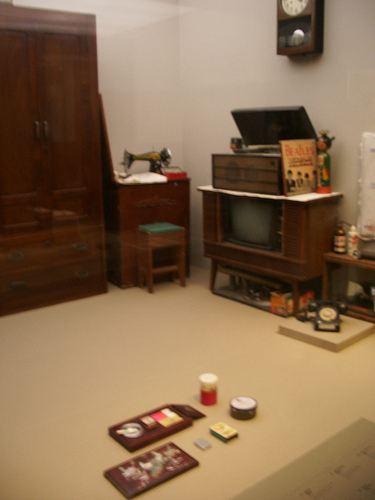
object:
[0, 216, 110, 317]
reflection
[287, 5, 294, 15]
number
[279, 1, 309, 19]
clock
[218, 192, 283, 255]
television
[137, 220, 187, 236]
cushion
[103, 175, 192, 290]
dresser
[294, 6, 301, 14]
black number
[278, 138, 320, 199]
record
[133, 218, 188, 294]
stool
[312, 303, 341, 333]
phone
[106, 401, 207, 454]
objects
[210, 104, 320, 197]
record player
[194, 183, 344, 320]
furniture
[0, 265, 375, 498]
floor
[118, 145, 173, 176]
sewing machine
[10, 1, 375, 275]
wall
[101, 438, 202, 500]
item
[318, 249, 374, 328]
stand